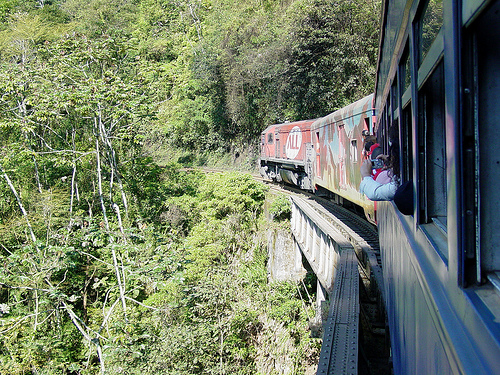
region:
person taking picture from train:
[357, 154, 407, 202]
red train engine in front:
[245, 119, 323, 196]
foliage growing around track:
[75, 45, 272, 328]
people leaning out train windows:
[352, 121, 387, 158]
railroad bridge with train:
[282, 200, 383, 373]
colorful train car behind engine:
[302, 118, 382, 192]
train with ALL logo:
[267, 127, 327, 167]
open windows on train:
[407, 79, 498, 267]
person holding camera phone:
[358, 146, 388, 177]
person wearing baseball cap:
[350, 126, 374, 138]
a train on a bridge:
[150, 27, 484, 374]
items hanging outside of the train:
[340, 126, 408, 216]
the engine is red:
[228, 110, 318, 177]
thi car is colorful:
[286, 114, 381, 207]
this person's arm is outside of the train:
[354, 156, 402, 206]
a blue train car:
[350, 54, 477, 365]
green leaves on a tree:
[22, 38, 253, 363]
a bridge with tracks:
[242, 194, 355, 362]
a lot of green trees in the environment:
[9, 17, 339, 87]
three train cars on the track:
[237, 78, 477, 269]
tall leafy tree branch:
[176, 0, 249, 138]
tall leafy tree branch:
[124, 11, 166, 102]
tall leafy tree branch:
[3, 35, 68, 164]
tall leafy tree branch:
[73, 68, 148, 203]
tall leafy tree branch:
[210, 249, 293, 366]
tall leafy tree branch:
[88, 180, 165, 350]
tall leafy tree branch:
[16, 236, 98, 358]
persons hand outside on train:
[353, 128, 414, 218]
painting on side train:
[313, 117, 351, 183]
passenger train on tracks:
[239, 18, 496, 320]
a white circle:
[281, 123, 306, 161]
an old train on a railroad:
[241, 5, 493, 372]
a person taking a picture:
[351, 142, 396, 203]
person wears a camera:
[361, 155, 381, 170]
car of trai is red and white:
[247, 116, 312, 186]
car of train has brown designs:
[302, 95, 372, 201]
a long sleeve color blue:
[352, 151, 394, 206]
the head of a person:
[356, 130, 388, 169]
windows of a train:
[370, 21, 497, 312]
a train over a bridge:
[258, 6, 497, 368]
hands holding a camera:
[356, 150, 398, 205]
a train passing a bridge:
[237, 0, 498, 371]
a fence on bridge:
[274, 183, 381, 370]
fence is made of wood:
[288, 194, 374, 371]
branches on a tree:
[17, 88, 144, 345]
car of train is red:
[256, 118, 313, 188]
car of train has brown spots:
[302, 93, 379, 216]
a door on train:
[309, 126, 326, 182]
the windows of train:
[356, 5, 498, 319]